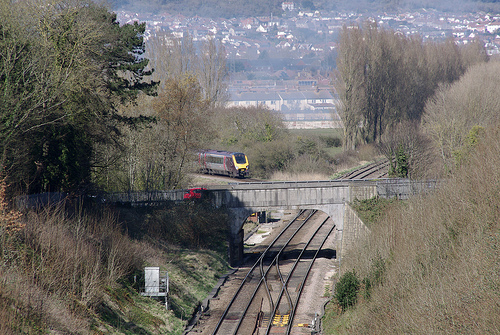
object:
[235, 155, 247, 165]
window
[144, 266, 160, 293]
box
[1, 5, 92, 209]
tree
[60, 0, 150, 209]
tree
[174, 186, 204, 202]
train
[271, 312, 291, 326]
tool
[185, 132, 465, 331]
track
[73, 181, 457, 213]
bridge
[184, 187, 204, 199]
paint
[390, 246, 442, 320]
plants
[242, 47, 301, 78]
hillside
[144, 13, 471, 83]
buildings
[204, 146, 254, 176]
train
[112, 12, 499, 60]
urban area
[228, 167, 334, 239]
crossway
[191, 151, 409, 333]
railway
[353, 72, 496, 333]
grass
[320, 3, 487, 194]
trees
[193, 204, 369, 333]
rail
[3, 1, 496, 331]
rural area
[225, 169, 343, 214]
road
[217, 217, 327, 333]
train tracks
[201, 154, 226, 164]
windows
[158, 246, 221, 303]
grass